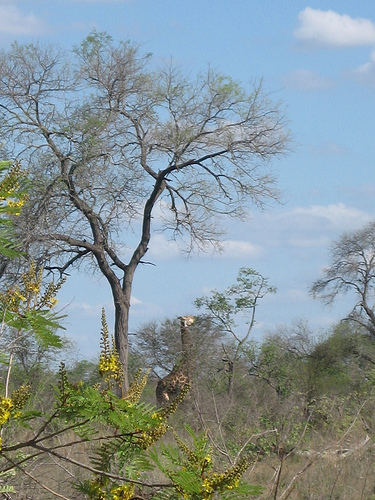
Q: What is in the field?
A: Giraffe.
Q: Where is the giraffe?
A: Field.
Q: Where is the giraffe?
A: Field.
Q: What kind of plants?
A: Wild.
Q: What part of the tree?
A: Branch.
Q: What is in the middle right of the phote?
A: Part of a tree.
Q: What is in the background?
A: A blue sky with white clouds.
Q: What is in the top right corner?
A: White clouds in a blue sky.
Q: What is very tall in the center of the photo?
A: A bare tree.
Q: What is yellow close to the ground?
A: A bush.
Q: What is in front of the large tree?
A: A bush with yellow flowers.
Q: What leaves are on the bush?
A: Green leaves.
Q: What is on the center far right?
A: A tree with no leaves.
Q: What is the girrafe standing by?
A: A tall tree with sparse leaves.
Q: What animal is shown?
A: A giraffe.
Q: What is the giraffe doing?
A: Walking.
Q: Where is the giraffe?
A: In the trees.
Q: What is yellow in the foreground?
A: Flowers.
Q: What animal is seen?
A: Giraffe.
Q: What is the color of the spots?
A: Brown.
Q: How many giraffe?
A: 1.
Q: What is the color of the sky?
A: Blue.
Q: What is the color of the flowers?
A: Yellow.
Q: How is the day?
A: Sunny.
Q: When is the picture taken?
A: Daytime.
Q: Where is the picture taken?
A: In Africa.